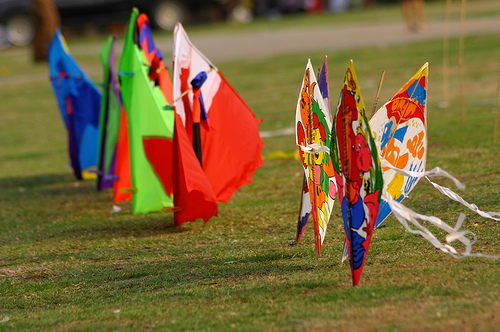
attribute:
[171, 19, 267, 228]
flag — red, white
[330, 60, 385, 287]
kite — red, colorful, here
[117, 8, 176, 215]
kite — green, standing, multicolored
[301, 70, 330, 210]
kid — purple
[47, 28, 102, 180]
kite — blue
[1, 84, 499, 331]
grass — short, here, green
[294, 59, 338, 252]
kite — green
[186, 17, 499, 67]
pavement — gray, grey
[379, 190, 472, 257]
string — here, white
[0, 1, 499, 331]
picture — daytime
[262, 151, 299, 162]
tail — yellow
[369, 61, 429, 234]
kite — blue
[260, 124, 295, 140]
line — white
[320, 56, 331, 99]
connector — blue